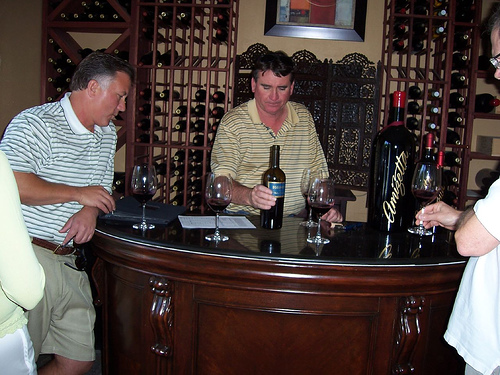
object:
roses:
[398, 41, 403, 45]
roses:
[212, 111, 217, 115]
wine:
[212, 90, 225, 101]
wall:
[1, 1, 497, 235]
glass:
[203, 172, 236, 243]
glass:
[297, 166, 328, 228]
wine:
[205, 198, 232, 211]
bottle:
[394, 23, 409, 35]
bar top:
[92, 212, 475, 269]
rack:
[368, 0, 500, 231]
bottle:
[365, 91, 415, 241]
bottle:
[368, 89, 419, 233]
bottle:
[443, 68, 470, 88]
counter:
[68, 201, 489, 375]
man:
[206, 51, 345, 223]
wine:
[129, 192, 156, 203]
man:
[0, 50, 139, 375]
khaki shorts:
[9, 243, 103, 364]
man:
[415, 0, 500, 375]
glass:
[123, 164, 158, 232]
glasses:
[405, 161, 446, 237]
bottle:
[156, 48, 179, 68]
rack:
[123, 0, 240, 216]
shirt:
[0, 90, 120, 246]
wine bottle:
[212, 90, 228, 103]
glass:
[305, 181, 337, 245]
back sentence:
[223, 41, 383, 195]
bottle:
[423, 88, 441, 98]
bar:
[0, 0, 500, 375]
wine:
[309, 203, 332, 213]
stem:
[315, 212, 323, 238]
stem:
[212, 208, 221, 237]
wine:
[410, 188, 440, 206]